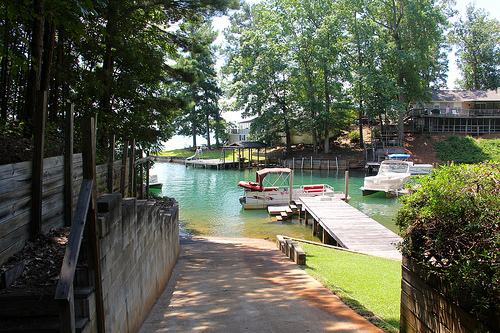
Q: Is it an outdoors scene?
A: Yes, it is outdoors.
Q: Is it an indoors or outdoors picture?
A: It is outdoors.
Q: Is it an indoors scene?
A: No, it is outdoors.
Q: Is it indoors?
A: No, it is outdoors.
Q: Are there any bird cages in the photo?
A: No, there are no bird cages.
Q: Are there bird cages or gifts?
A: No, there are no bird cages or gifts.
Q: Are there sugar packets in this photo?
A: No, there are no sugar packets.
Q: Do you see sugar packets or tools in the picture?
A: No, there are no sugar packets or tools.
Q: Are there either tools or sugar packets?
A: No, there are no sugar packets or tools.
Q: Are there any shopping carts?
A: No, there are no shopping carts.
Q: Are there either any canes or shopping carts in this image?
A: No, there are no shopping carts or canes.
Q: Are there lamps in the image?
A: No, there are no lamps.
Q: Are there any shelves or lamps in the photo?
A: No, there are no lamps or shelves.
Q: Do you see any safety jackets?
A: No, there are no safety jackets.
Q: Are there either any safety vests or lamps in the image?
A: No, there are no safety vests or lamps.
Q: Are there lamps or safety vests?
A: No, there are no safety vests or lamps.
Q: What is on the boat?
A: The canopy is on the boat.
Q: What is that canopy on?
A: The canopy is on the boat.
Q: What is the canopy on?
A: The canopy is on the boat.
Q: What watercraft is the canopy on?
A: The canopy is on the boat.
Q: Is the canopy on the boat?
A: Yes, the canopy is on the boat.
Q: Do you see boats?
A: Yes, there is a boat.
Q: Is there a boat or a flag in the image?
A: Yes, there is a boat.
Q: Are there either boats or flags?
A: Yes, there is a boat.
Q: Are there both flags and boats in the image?
A: No, there is a boat but no flags.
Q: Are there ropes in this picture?
A: No, there are no ropes.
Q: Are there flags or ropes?
A: No, there are no ropes or flags.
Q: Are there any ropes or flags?
A: No, there are no ropes or flags.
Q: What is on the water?
A: The boat is on the water.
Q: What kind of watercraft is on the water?
A: The watercraft is a boat.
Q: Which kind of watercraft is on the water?
A: The watercraft is a boat.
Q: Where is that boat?
A: The boat is on the water.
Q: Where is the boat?
A: The boat is on the water.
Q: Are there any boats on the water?
A: Yes, there is a boat on the water.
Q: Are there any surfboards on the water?
A: No, there is a boat on the water.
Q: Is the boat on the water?
A: Yes, the boat is on the water.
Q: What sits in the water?
A: The boat sits in the water.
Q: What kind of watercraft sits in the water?
A: The watercraft is a boat.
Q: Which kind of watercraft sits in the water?
A: The watercraft is a boat.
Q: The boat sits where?
A: The boat sits in the water.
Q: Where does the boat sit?
A: The boat sits in the water.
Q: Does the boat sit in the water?
A: Yes, the boat sits in the water.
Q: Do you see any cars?
A: No, there are no cars.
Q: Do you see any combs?
A: No, there are no combs.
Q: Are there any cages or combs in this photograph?
A: No, there are no combs or cages.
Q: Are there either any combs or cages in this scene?
A: No, there are no combs or cages.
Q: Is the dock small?
A: Yes, the dock is small.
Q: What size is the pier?
A: The pier is small.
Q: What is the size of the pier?
A: The pier is small.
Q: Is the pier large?
A: No, the pier is small.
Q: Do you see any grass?
A: Yes, there is grass.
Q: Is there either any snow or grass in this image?
A: Yes, there is grass.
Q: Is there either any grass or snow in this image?
A: Yes, there is grass.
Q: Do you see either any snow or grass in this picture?
A: Yes, there is grass.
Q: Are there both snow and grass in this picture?
A: No, there is grass but no snow.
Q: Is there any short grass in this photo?
A: Yes, there is short grass.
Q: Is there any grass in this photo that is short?
A: Yes, there is grass that is short.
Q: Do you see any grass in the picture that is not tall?
A: Yes, there is short grass.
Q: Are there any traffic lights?
A: No, there are no traffic lights.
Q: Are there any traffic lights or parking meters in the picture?
A: No, there are no traffic lights or parking meters.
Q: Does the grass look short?
A: Yes, the grass is short.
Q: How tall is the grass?
A: The grass is short.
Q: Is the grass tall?
A: No, the grass is short.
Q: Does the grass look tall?
A: No, the grass is short.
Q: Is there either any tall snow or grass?
A: No, there is grass but it is short.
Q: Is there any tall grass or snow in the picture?
A: No, there is grass but it is short.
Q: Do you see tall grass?
A: No, there is grass but it is short.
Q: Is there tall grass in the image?
A: No, there is grass but it is short.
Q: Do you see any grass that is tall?
A: No, there is grass but it is short.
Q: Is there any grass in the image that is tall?
A: No, there is grass but it is short.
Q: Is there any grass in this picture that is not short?
A: No, there is grass but it is short.